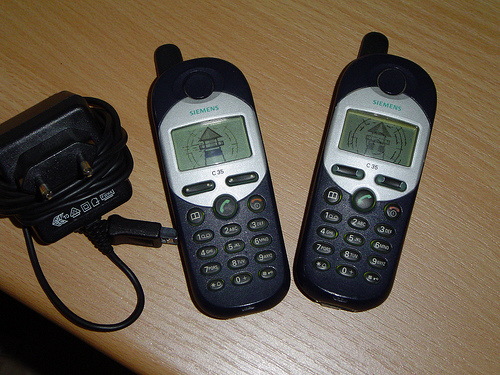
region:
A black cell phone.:
[283, 22, 450, 319]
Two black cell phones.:
[125, 15, 455, 328]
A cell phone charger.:
[6, 81, 174, 346]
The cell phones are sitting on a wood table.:
[127, 0, 467, 370]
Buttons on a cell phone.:
[176, 175, 286, 296]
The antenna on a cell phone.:
[120, 22, 197, 72]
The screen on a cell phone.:
[335, 97, 425, 167]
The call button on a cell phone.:
[210, 195, 240, 220]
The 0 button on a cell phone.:
[227, 270, 249, 292]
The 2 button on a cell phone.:
[347, 209, 369, 231]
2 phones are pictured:
[130, 30, 427, 325]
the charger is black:
[2, 96, 177, 281]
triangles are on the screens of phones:
[184, 108, 432, 188]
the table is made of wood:
[0, 2, 491, 367]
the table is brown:
[2, 3, 494, 365]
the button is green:
[202, 191, 242, 222]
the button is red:
[246, 194, 266, 216]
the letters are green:
[178, 99, 238, 125]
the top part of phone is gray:
[159, 100, 281, 216]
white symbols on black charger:
[42, 181, 132, 238]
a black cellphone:
[288, 33, 455, 371]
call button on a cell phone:
[348, 185, 378, 218]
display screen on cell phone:
[333, 108, 425, 168]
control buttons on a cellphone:
[304, 166, 419, 296]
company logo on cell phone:
[365, 91, 412, 113]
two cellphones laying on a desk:
[146, 20, 449, 330]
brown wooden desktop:
[23, 7, 119, 87]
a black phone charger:
[2, 63, 129, 243]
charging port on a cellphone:
[225, 292, 288, 338]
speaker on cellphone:
[174, 61, 218, 107]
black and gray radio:
[330, 55, 431, 317]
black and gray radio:
[150, 65, 280, 316]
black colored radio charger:
[4, 90, 163, 305]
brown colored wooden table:
[144, 320, 454, 373]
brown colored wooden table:
[20, 8, 137, 80]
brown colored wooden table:
[251, 7, 320, 109]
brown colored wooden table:
[405, 9, 487, 60]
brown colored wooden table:
[435, 173, 491, 373]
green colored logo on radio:
[183, 103, 226, 119]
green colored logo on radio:
[371, 94, 406, 117]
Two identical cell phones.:
[148, 31, 440, 319]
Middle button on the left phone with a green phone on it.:
[213, 193, 236, 220]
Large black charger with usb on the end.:
[0, 90, 180, 330]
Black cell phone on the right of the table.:
[291, 29, 437, 316]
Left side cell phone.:
[147, 44, 292, 321]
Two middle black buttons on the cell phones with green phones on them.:
[215, 184, 375, 219]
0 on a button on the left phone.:
[230, 273, 252, 284]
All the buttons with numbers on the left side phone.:
[193, 216, 275, 286]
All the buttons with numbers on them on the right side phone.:
[312, 208, 396, 278]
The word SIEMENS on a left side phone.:
[188, 104, 221, 119]